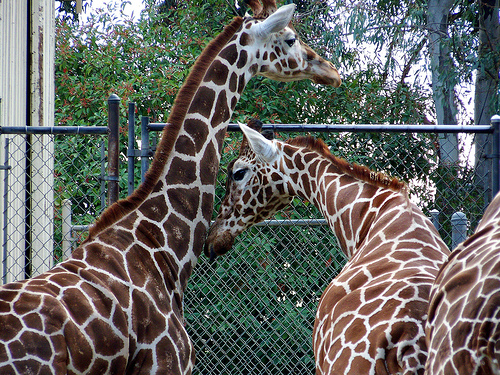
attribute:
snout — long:
[276, 22, 360, 104]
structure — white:
[12, 24, 84, 284]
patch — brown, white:
[291, 154, 325, 200]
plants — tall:
[44, 0, 498, 375]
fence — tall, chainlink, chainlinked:
[1, 89, 498, 374]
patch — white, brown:
[127, 240, 174, 314]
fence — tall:
[229, 230, 296, 300]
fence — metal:
[13, 122, 490, 318]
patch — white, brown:
[313, 342, 328, 366]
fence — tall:
[18, 80, 483, 371]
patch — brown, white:
[369, 205, 420, 245]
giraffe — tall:
[1, 1, 483, 371]